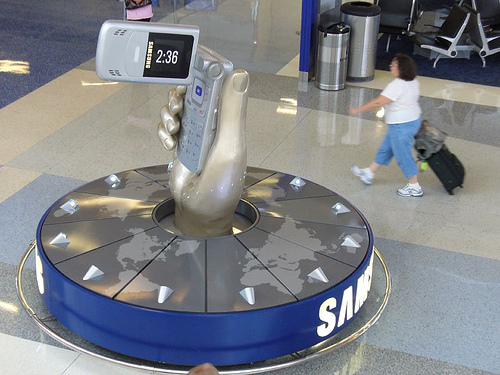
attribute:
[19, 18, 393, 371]
display — cellular phone, samsung, cell phone, right hand, white, sundial, blue, round, object, silver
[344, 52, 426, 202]
lady — plump, middle aged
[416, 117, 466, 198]
backpack — black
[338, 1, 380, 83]
trash receptical — silver, black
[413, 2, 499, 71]
seats — silver, black, empty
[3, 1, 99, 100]
carpet — blue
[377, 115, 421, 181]
pants — blue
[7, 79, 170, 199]
floor — gray, tiled, blue, beige, lined, tile, blue,gray,white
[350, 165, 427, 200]
sneakers — white, blue, athletic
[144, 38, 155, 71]
letters — large, white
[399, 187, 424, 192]
stripes — blue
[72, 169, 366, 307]
world map — gray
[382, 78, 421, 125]
shirt — white, short sleeve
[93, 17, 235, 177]
phone — black, large, cell phone, silver, held, statue, samsung, stand, giant, fake, cellphone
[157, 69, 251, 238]
hand — statue, fake, large, giant, plastic, silvertone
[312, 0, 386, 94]
trash receptical — pair, metal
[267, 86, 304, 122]
reflection — light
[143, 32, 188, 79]
clock face — world image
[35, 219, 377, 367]
base — blue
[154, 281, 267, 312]
cones — silver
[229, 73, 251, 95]
fingernail — unpolished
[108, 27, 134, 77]
vents — diagonal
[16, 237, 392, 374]
circle — big, silvertone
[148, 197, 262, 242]
circle — small, silvertone